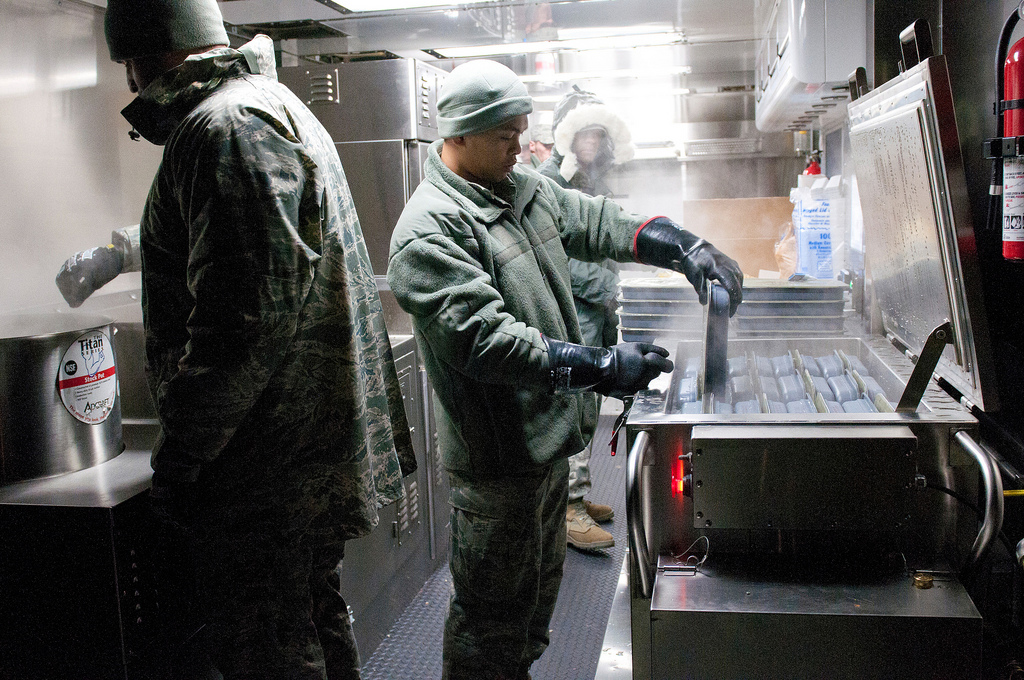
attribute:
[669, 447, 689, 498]
redglow — red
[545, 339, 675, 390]
glove — black , Large 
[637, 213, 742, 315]
glove — Large , black 